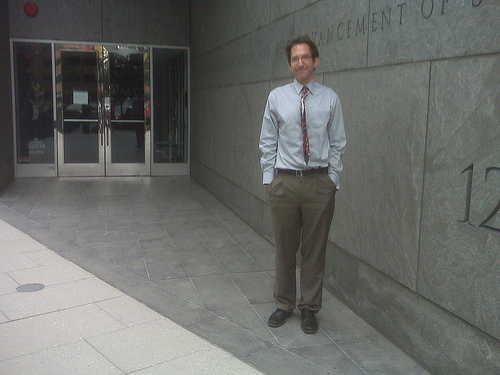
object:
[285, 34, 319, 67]
hair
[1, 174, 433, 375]
concrete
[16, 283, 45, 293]
grate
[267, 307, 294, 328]
shoes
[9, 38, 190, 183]
office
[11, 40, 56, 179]
doors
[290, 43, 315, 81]
face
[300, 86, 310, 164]
tie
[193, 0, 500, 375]
wall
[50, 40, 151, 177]
door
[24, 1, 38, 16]
alarm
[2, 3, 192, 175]
side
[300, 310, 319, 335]
shoes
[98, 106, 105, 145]
handles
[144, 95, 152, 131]
reflection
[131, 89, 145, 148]
reflection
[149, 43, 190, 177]
door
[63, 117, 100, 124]
rail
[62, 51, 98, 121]
glass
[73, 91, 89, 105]
sign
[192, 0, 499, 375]
granite side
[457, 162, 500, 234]
number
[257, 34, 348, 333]
man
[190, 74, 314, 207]
stones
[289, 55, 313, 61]
eye glasses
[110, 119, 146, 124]
rails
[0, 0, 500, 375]
building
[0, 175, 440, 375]
flooring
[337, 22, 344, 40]
writing